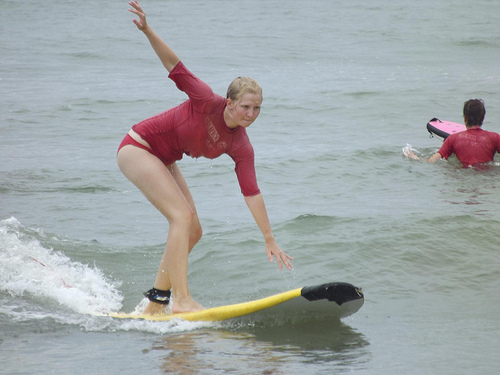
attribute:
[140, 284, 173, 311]
ankle tie — black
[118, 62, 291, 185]
shirt — red 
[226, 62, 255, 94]
hair — wet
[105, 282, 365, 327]
surfboard — yellow and black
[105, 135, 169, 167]
bikini — red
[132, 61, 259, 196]
shirt — red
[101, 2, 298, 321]
surfer — female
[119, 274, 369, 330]
surfboard — yellow black and white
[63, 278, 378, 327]
surfboard — yellow and white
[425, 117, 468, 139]
surfboard — pin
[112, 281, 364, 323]
surfboard — yellow, black, and white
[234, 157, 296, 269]
arm — extended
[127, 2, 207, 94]
arm — extended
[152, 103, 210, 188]
shirt — red